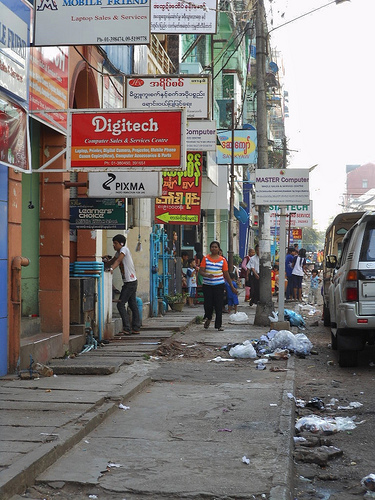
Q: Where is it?
A: This is at the sidewalk.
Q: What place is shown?
A: It is a sidewalk.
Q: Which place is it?
A: It is a sidewalk.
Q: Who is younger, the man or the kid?
A: The kid is younger than the man.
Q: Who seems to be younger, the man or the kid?
A: The kid is younger than the man.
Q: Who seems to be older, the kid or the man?
A: The man is older than the kid.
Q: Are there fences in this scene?
A: No, there are no fences.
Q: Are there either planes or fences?
A: No, there are no fences or planes.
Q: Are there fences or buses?
A: No, there are no fences or buses.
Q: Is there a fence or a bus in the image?
A: No, there are no fences or buses.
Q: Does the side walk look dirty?
A: Yes, the side walk is dirty.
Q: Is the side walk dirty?
A: Yes, the side walk is dirty.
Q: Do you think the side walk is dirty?
A: Yes, the side walk is dirty.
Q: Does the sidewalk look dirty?
A: Yes, the sidewalk is dirty.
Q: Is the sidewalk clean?
A: No, the sidewalk is dirty.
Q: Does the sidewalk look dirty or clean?
A: The sidewalk is dirty.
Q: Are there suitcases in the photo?
A: No, there are no suitcases.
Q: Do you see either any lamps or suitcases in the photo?
A: No, there are no suitcases or lamps.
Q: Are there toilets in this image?
A: No, there are no toilets.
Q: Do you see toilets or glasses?
A: No, there are no toilets or glasses.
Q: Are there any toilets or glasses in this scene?
A: No, there are no toilets or glasses.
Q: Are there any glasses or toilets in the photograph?
A: No, there are no toilets or glasses.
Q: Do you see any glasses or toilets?
A: No, there are no toilets or glasses.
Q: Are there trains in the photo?
A: No, there are no trains.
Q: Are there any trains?
A: No, there are no trains.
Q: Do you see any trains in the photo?
A: No, there are no trains.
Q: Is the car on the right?
A: Yes, the car is on the right of the image.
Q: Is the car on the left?
A: No, the car is on the right of the image.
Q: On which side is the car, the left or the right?
A: The car is on the right of the image.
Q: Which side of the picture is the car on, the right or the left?
A: The car is on the right of the image.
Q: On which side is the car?
A: The car is on the right of the image.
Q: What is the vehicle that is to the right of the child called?
A: The vehicle is a car.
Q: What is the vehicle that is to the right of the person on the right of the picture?
A: The vehicle is a car.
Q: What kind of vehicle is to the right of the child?
A: The vehicle is a car.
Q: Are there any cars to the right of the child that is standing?
A: Yes, there is a car to the right of the child.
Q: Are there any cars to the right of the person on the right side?
A: Yes, there is a car to the right of the child.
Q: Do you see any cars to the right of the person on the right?
A: Yes, there is a car to the right of the child.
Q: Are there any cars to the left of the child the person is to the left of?
A: No, the car is to the right of the child.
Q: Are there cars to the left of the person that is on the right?
A: No, the car is to the right of the child.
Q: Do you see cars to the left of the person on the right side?
A: No, the car is to the right of the child.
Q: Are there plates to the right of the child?
A: No, there is a car to the right of the child.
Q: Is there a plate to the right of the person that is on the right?
A: No, there is a car to the right of the child.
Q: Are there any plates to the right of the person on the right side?
A: No, there is a car to the right of the child.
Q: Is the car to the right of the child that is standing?
A: Yes, the car is to the right of the child.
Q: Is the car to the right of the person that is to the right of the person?
A: Yes, the car is to the right of the child.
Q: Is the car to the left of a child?
A: No, the car is to the right of a child.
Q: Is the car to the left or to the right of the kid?
A: The car is to the right of the kid.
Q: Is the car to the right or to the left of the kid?
A: The car is to the right of the kid.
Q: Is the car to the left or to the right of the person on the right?
A: The car is to the right of the kid.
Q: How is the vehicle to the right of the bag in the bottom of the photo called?
A: The vehicle is a car.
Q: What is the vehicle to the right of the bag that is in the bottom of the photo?
A: The vehicle is a car.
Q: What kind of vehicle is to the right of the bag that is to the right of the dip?
A: The vehicle is a car.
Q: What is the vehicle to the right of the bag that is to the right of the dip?
A: The vehicle is a car.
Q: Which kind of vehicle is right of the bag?
A: The vehicle is a car.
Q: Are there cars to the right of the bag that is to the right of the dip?
A: Yes, there is a car to the right of the bag.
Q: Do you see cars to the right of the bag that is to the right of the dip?
A: Yes, there is a car to the right of the bag.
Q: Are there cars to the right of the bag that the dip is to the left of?
A: Yes, there is a car to the right of the bag.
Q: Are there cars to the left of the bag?
A: No, the car is to the right of the bag.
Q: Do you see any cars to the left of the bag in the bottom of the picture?
A: No, the car is to the right of the bag.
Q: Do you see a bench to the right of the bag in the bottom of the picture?
A: No, there is a car to the right of the bag.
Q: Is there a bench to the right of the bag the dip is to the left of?
A: No, there is a car to the right of the bag.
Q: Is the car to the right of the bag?
A: Yes, the car is to the right of the bag.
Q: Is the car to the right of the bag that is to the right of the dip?
A: Yes, the car is to the right of the bag.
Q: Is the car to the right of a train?
A: No, the car is to the right of the bag.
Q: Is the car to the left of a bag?
A: No, the car is to the right of a bag.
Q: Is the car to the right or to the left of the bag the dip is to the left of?
A: The car is to the right of the bag.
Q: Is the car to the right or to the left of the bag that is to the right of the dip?
A: The car is to the right of the bag.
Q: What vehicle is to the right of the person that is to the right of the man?
A: The vehicle is a car.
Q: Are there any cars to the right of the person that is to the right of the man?
A: Yes, there is a car to the right of the person.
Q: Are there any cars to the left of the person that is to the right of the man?
A: No, the car is to the right of the person.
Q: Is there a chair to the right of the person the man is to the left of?
A: No, there is a car to the right of the person.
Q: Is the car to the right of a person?
A: Yes, the car is to the right of a person.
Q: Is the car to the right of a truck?
A: No, the car is to the right of a person.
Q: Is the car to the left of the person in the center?
A: No, the car is to the right of the person.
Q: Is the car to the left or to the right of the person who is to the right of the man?
A: The car is to the right of the person.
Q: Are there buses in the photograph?
A: No, there are no buses.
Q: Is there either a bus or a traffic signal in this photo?
A: No, there are no buses or traffic lights.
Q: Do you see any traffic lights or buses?
A: No, there are no buses or traffic lights.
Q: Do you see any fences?
A: No, there are no fences.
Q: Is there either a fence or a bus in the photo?
A: No, there are no fences or buses.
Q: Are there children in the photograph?
A: Yes, there is a child.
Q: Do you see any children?
A: Yes, there is a child.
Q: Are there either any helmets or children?
A: Yes, there is a child.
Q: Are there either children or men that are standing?
A: Yes, the child is standing.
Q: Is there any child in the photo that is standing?
A: Yes, there is a child that is standing.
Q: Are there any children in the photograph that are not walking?
A: Yes, there is a child that is standing.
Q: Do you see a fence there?
A: No, there are no fences.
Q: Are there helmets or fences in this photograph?
A: No, there are no fences or helmets.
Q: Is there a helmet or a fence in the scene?
A: No, there are no fences or helmets.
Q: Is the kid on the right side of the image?
A: Yes, the kid is on the right of the image.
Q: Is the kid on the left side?
A: No, the kid is on the right of the image.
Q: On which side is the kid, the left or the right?
A: The kid is on the right of the image.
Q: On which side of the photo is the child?
A: The child is on the right of the image.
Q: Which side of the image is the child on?
A: The child is on the right of the image.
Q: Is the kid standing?
A: Yes, the kid is standing.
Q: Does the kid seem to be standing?
A: Yes, the kid is standing.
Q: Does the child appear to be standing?
A: Yes, the child is standing.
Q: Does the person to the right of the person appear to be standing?
A: Yes, the child is standing.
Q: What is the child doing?
A: The child is standing.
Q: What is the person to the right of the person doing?
A: The child is standing.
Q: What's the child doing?
A: The child is standing.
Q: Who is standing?
A: The kid is standing.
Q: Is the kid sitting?
A: No, the kid is standing.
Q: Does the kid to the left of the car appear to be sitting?
A: No, the child is standing.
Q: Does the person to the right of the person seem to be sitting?
A: No, the child is standing.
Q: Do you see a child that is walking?
A: No, there is a child but he is standing.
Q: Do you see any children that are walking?
A: No, there is a child but he is standing.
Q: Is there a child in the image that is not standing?
A: No, there is a child but he is standing.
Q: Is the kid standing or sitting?
A: The kid is standing.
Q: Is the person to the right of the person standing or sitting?
A: The kid is standing.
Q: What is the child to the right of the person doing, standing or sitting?
A: The kid is standing.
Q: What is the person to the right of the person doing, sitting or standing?
A: The kid is standing.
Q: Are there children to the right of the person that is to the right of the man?
A: Yes, there is a child to the right of the person.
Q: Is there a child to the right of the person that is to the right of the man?
A: Yes, there is a child to the right of the person.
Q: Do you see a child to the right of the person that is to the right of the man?
A: Yes, there is a child to the right of the person.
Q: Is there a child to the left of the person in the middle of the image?
A: No, the child is to the right of the person.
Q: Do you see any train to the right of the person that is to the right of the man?
A: No, there is a child to the right of the person.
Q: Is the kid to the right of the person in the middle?
A: Yes, the kid is to the right of the person.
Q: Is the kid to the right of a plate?
A: No, the kid is to the right of the person.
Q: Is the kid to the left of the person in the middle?
A: No, the kid is to the right of the person.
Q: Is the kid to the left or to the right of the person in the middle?
A: The kid is to the right of the person.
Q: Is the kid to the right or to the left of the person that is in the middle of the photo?
A: The kid is to the right of the person.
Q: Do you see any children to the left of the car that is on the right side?
A: Yes, there is a child to the left of the car.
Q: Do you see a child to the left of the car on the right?
A: Yes, there is a child to the left of the car.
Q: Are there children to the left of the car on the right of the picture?
A: Yes, there is a child to the left of the car.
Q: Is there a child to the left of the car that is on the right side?
A: Yes, there is a child to the left of the car.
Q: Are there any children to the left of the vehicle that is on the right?
A: Yes, there is a child to the left of the car.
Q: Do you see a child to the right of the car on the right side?
A: No, the child is to the left of the car.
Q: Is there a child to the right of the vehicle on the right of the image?
A: No, the child is to the left of the car.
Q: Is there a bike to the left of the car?
A: No, there is a child to the left of the car.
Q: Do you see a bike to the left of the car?
A: No, there is a child to the left of the car.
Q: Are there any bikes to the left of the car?
A: No, there is a child to the left of the car.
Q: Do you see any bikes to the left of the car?
A: No, there is a child to the left of the car.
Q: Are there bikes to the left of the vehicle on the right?
A: No, there is a child to the left of the car.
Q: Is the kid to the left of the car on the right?
A: Yes, the kid is to the left of the car.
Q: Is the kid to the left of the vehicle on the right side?
A: Yes, the kid is to the left of the car.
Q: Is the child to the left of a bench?
A: No, the child is to the left of the car.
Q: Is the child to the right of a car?
A: No, the child is to the left of a car.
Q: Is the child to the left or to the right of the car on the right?
A: The child is to the left of the car.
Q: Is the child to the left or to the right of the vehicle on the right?
A: The child is to the left of the car.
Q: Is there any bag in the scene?
A: Yes, there is a bag.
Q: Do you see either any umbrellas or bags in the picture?
A: Yes, there is a bag.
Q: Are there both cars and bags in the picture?
A: Yes, there are both a bag and a car.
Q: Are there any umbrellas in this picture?
A: No, there are no umbrellas.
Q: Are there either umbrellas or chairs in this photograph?
A: No, there are no umbrellas or chairs.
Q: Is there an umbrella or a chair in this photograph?
A: No, there are no umbrellas or chairs.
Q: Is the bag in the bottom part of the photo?
A: Yes, the bag is in the bottom of the image.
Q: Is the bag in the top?
A: No, the bag is in the bottom of the image.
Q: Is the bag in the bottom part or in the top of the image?
A: The bag is in the bottom of the image.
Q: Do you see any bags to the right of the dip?
A: Yes, there is a bag to the right of the dip.